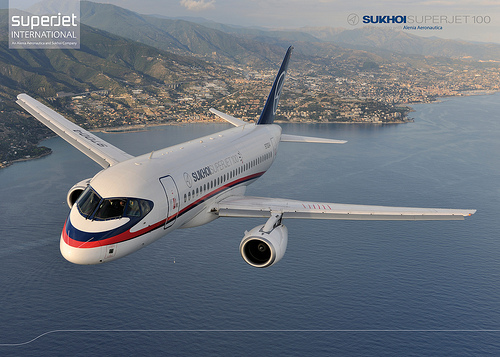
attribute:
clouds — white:
[248, 9, 308, 41]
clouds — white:
[182, 1, 498, 61]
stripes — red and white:
[65, 169, 275, 251]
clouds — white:
[176, 1, 346, 20]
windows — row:
[179, 144, 271, 210]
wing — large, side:
[214, 188, 499, 250]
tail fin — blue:
[254, 40, 294, 125]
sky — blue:
[295, 10, 325, 45]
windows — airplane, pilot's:
[70, 184, 150, 224]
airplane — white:
[21, 44, 479, 272]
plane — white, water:
[15, 45, 477, 268]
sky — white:
[106, 1, 496, 44]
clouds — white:
[178, 0, 213, 10]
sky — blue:
[101, 0, 499, 47]